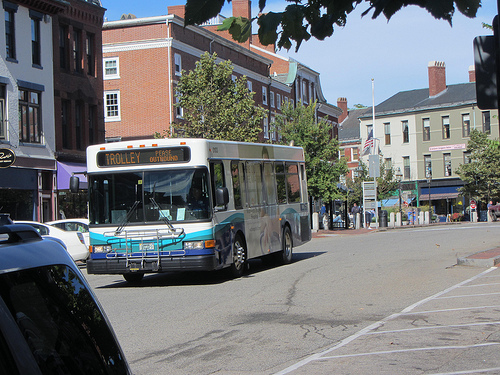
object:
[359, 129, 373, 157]
flag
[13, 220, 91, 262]
car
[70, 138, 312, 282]
bus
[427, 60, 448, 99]
chimney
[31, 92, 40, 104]
window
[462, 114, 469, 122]
curtain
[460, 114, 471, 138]
window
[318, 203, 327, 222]
person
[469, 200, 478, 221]
sign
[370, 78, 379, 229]
pole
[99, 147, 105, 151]
light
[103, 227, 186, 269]
rack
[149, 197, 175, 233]
wiper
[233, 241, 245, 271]
hubcap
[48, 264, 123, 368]
reflection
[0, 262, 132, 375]
window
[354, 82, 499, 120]
roof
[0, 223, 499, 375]
street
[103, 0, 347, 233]
building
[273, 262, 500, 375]
line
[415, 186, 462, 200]
awning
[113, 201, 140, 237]
wiper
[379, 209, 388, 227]
barrel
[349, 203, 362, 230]
person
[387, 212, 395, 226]
barricade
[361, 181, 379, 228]
sign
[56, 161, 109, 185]
awning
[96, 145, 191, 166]
display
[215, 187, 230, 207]
mirror